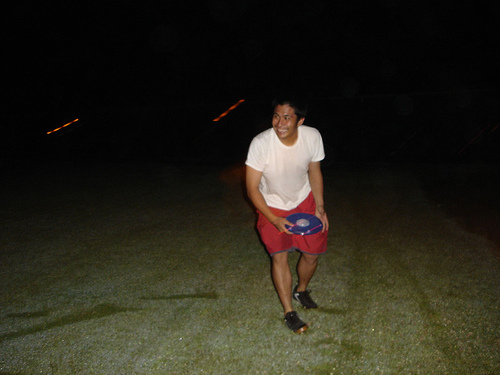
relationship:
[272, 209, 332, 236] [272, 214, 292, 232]
freesbie in hand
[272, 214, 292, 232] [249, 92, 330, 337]
hand of man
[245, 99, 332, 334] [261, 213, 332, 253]
guy wearing shorts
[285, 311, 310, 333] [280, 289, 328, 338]
shoe on feet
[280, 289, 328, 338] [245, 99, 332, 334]
feet of guy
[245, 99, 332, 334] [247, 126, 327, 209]
guy wearing shirt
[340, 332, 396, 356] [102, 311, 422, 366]
turf on ground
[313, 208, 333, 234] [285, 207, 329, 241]
hand touching frisbee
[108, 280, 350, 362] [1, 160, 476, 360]
lines on ground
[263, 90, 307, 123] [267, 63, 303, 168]
hair on head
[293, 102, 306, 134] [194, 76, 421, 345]
ear on man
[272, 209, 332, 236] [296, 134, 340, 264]
freesbie in hand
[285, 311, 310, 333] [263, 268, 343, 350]
shoe on foot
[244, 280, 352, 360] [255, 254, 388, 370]
shoe on foot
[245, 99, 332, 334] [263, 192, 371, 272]
guy playing frisbee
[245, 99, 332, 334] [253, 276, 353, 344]
guy wearing shoes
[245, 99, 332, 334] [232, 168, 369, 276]
guy wearing shorts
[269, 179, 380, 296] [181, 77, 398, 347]
freesbie held by man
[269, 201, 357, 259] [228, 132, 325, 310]
freesbie in hand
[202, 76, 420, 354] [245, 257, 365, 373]
guy wearing shoes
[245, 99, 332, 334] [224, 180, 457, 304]
guy wearing shorts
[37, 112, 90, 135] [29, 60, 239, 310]
lights shining on field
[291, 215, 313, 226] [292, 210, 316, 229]
circle on freezbie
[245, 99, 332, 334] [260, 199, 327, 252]
guy wearing shorts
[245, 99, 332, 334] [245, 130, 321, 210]
guy wearing shirt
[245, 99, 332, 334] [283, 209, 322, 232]
guy holding frisbee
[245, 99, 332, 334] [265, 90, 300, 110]
guy with hair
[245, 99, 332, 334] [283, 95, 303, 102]
guy with hair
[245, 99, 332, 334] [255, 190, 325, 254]
guy wearing shorts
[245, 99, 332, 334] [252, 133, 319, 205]
guy wearing shirt